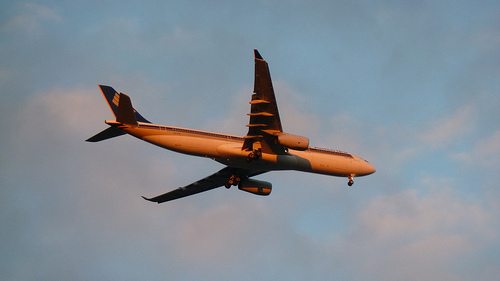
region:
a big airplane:
[87, 78, 459, 203]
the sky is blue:
[300, 42, 478, 112]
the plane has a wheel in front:
[338, 172, 365, 188]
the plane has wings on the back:
[84, 84, 152, 149]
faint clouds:
[352, 128, 492, 278]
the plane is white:
[72, 49, 451, 230]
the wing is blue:
[95, 75, 157, 126]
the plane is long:
[53, 90, 499, 198]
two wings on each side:
[144, 69, 341, 226]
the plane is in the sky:
[84, 47, 374, 202]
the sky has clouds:
[1, 0, 496, 278]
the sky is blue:
[0, 3, 499, 279]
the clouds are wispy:
[0, 0, 499, 278]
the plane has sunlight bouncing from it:
[86, 49, 376, 203]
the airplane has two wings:
[141, 49, 279, 205]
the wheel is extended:
[346, 175, 355, 185]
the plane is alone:
[86, 49, 376, 202]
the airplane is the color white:
[85, 49, 378, 202]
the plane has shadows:
[85, 44, 377, 201]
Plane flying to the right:
[87, 47, 377, 205]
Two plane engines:
[238, 134, 310, 196]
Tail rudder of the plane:
[95, 80, 155, 125]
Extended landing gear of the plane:
[225, 148, 356, 193]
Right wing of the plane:
[241, 47, 286, 149]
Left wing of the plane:
[141, 168, 272, 204]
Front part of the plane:
[290, 145, 377, 180]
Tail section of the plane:
[80, 82, 154, 147]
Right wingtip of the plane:
[250, 47, 271, 61]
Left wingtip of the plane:
[142, 192, 159, 204]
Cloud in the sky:
[356, 190, 476, 262]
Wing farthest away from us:
[142, 183, 233, 210]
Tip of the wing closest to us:
[248, 41, 271, 72]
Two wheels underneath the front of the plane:
[343, 176, 357, 188]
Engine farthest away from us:
[233, 173, 275, 197]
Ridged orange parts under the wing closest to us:
[241, 93, 263, 141]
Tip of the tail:
[91, 82, 116, 107]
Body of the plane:
[176, 133, 330, 174]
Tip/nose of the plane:
[356, 152, 376, 183]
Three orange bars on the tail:
[111, 89, 118, 106]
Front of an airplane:
[310, 133, 380, 189]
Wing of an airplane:
[240, 36, 286, 138]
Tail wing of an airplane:
[90, 77, 146, 122]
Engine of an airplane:
[237, 172, 273, 198]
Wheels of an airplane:
[344, 175, 357, 188]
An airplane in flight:
[87, 47, 381, 209]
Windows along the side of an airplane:
[136, 120, 246, 143]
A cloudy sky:
[286, 10, 489, 127]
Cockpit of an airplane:
[354, 149, 379, 184]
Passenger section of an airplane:
[155, 122, 315, 169]